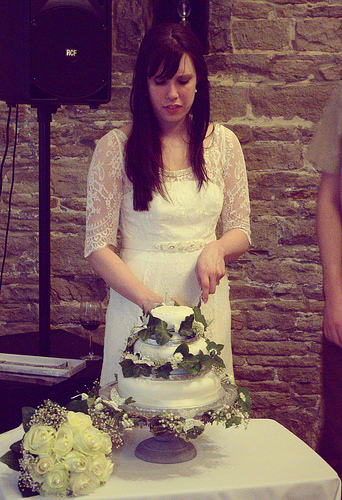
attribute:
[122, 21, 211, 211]
hair — auburn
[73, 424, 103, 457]
rose — white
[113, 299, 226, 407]
cake — three tiers, wedding cake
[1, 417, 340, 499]
table cloth — white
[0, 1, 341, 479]
wall — brick, stone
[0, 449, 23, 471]
leaf — green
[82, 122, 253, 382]
bridal gown — white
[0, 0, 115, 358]
speaker — tall